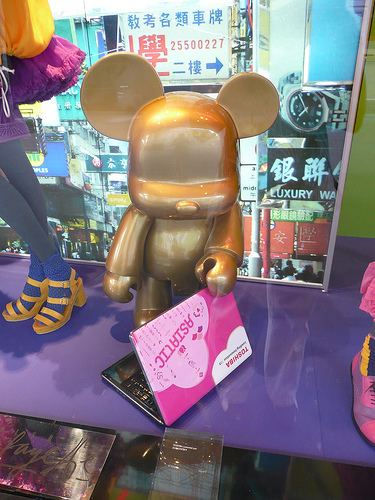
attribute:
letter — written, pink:
[160, 344, 179, 362]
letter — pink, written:
[184, 315, 193, 328]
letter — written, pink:
[170, 334, 179, 346]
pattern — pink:
[52, 262, 69, 275]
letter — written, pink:
[126, 279, 256, 429]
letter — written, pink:
[228, 357, 233, 365]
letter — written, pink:
[136, 291, 262, 405]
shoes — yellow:
[3, 266, 86, 334]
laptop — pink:
[99, 283, 255, 425]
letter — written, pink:
[179, 321, 190, 334]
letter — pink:
[149, 352, 167, 370]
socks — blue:
[18, 238, 77, 336]